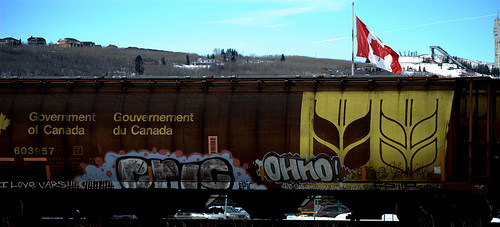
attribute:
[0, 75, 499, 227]
train — yellow, brown, freight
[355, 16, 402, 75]
flag — canadian, white, red, waving, blowing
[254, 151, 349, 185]
graffiti — white, black, spray painted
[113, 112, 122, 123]
letter — yellow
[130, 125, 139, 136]
letter — yellow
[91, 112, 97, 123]
letter — yellow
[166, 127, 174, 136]
letter — yellow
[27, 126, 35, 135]
letter — yellow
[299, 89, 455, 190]
picture — yellow, printed, logo, wheat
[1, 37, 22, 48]
building — ancient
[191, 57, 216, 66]
building — ancient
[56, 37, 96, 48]
building — ancient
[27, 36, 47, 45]
building — ancient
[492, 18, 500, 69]
building — gray, ancient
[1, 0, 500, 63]
sky — blue, daytime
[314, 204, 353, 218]
car — parked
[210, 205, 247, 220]
car — parked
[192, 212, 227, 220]
car — parked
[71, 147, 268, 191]
graffiti — black, white, spray painted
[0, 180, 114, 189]
graffiti — white, spray painted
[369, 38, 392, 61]
leaf — maple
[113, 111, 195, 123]
word — yellow, printed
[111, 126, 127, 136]
word — yellow, printed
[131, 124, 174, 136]
word — yellow, printed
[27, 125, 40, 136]
word — yellow, printed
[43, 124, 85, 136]
word — yellow, printed